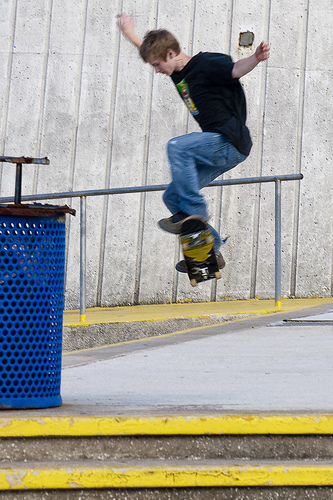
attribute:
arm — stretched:
[198, 39, 271, 79]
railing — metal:
[1, 171, 303, 206]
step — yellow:
[1, 414, 321, 437]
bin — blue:
[11, 221, 62, 411]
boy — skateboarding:
[119, 26, 274, 337]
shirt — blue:
[183, 52, 261, 149]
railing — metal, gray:
[69, 182, 129, 322]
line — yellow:
[27, 412, 306, 448]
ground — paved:
[173, 352, 310, 411]